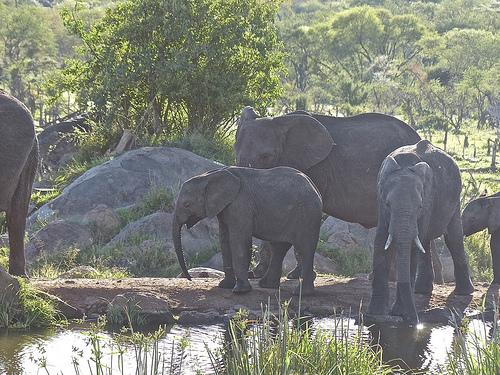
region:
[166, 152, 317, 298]
A baby elephant near water.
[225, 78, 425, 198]
The bigger elephant is hidden by the two little elephants.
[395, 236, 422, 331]
The elephant has his trunk in water.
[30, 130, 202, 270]
Large boulders behind the elephants.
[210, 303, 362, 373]
Green plants in the foreground.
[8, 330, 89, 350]
The water is greenish blue.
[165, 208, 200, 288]
A trunk on the baby elephant.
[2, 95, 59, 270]
Part of an elephant is visible.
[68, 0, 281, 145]
A tree behind the elephants.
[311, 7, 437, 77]
Trees growing in the distance.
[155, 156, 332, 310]
baby elephant by the water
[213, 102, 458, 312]
adult elephant by baby elephant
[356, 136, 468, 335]
elephant looking at camera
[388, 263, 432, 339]
elephant trunk in water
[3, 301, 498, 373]
sunlight reflecting in water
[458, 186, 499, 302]
tiny elephant in back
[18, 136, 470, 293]
large rock pile behind elephants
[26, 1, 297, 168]
large tree behind rocks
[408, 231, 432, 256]
husk beside elephant trunk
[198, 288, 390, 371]
weeds growing up from water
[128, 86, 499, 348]
Four elephants near the water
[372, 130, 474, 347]
An elephant with its trunk in the water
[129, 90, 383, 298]
A young elephant beside its mother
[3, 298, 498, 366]
A water hole for elephants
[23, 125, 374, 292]
A large rock behind the elephants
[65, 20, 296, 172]
A large tree behind the rock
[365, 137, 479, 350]
Two white tusks on an elephant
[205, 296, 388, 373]
Grass near the water hole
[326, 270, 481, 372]
Sun shining on the water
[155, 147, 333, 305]
The elephant's mouth is wet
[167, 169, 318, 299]
a small grey elephant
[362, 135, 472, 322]
a large grey elephant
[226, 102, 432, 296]
a large grey elephant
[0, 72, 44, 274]
a large grey elephant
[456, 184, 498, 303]
a small grey elephant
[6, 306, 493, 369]
a small stream of water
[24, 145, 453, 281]
a large grey boulder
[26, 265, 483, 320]
a small dirt path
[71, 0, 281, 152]
large green tree in foreground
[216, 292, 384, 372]
patch of tall grass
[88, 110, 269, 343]
big stones are visible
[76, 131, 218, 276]
big stones are visible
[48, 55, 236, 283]
big stones are visible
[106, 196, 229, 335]
big stones are visible